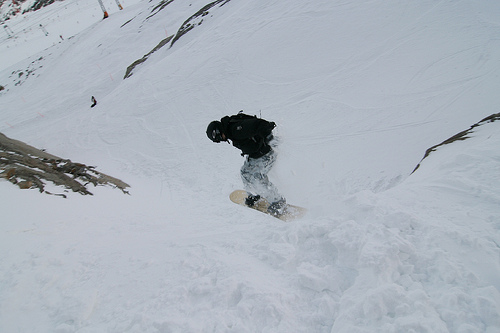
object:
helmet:
[205, 119, 222, 144]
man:
[205, 109, 289, 218]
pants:
[240, 150, 285, 205]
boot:
[244, 194, 262, 209]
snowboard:
[228, 189, 309, 224]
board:
[228, 188, 309, 225]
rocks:
[0, 130, 131, 201]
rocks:
[119, 0, 176, 29]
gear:
[219, 109, 275, 159]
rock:
[407, 109, 500, 176]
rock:
[122, 0, 234, 81]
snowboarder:
[89, 95, 98, 109]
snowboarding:
[204, 109, 309, 223]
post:
[114, 0, 124, 11]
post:
[95, 0, 110, 20]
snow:
[3, 1, 498, 332]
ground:
[0, 1, 498, 332]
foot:
[244, 190, 262, 208]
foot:
[263, 197, 288, 218]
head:
[204, 116, 226, 144]